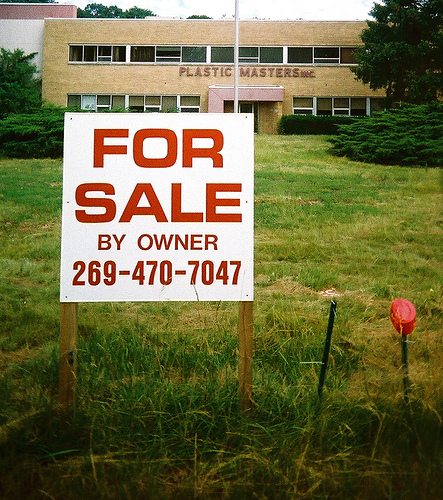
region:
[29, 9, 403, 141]
a very large brick building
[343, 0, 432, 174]
very large tree in front of a brick building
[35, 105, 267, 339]
white for sale sign with the letter f on it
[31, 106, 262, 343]
white for sale sign with the letter o on it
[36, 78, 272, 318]
white for sale sign with the letter r on it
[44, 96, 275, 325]
white for sale sign with the letter s on it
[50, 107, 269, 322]
white for sale sign with the letter a on it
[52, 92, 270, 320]
white for sale sign with the letter l on it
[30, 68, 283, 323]
white for sale sign with the letter e on it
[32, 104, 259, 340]
white for sale sign with the letter b on it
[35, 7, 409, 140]
tan colored two-story building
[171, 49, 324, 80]
name or corporation above entrance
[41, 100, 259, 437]
red and white sign held up with two pieces of wood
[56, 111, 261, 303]
sign giving property and contact information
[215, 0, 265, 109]
pole in front of building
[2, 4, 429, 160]
trees and shrubs on the sides of the building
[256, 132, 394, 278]
lawn in various colors and heights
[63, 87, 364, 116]
shades partially pulled down on lower windows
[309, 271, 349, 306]
part of a sign embedded in grass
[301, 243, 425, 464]
short black poles and a cap on the grass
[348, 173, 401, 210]
part of a ground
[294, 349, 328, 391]
part of a fence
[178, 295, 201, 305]
edge of a board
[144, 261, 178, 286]
part of a number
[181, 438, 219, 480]
part of a grass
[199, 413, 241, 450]
part of a field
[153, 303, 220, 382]
part of a fence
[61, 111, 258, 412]
Sale sign on a lawn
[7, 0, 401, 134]
a concrete building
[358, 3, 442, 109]
tree in front of building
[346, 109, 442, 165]
shrub near a tree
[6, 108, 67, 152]
shrub beside building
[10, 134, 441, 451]
lawn in front of building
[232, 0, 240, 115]
pole in front of building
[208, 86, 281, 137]
Entrance to the building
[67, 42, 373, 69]
windows on the upper floor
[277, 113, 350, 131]
shrub fence in front of building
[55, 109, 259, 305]
The white 'for sale' sign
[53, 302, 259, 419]
The posts holding up the for sale sign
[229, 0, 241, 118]
The pole in front of the building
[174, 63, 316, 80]
The writing on the building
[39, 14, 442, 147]
The brown building in the background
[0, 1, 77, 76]
The white and red building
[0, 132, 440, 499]
The green lawn in front of the building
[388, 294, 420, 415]
The pole with the red end on it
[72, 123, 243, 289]
The red writing on the sign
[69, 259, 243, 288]
The phone number on the sign